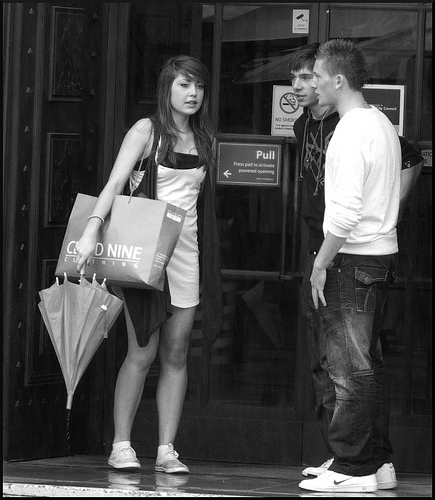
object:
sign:
[358, 84, 406, 137]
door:
[4, 2, 109, 463]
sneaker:
[297, 472, 376, 492]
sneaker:
[376, 464, 398, 489]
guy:
[286, 41, 425, 478]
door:
[300, 0, 422, 473]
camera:
[295, 12, 308, 22]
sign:
[271, 82, 305, 137]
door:
[200, 3, 320, 465]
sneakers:
[105, 437, 193, 480]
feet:
[107, 446, 141, 470]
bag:
[55, 116, 188, 291]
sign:
[216, 141, 281, 186]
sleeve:
[324, 145, 366, 240]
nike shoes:
[296, 469, 377, 492]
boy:
[297, 38, 403, 493]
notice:
[291, 8, 309, 35]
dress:
[110, 132, 212, 310]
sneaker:
[295, 471, 380, 495]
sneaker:
[302, 457, 336, 477]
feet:
[297, 469, 378, 492]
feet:
[376, 462, 397, 490]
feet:
[300, 454, 334, 477]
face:
[170, 75, 204, 116]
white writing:
[63, 238, 143, 270]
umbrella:
[38, 240, 124, 410]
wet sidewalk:
[15, 459, 305, 492]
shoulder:
[126, 115, 162, 147]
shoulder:
[329, 112, 360, 158]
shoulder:
[291, 110, 311, 142]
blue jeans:
[315, 252, 394, 476]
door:
[101, 1, 202, 461]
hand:
[75, 228, 98, 275]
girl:
[74, 52, 217, 474]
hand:
[309, 262, 327, 310]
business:
[0, 0, 434, 498]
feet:
[155, 451, 191, 474]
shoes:
[106, 440, 142, 471]